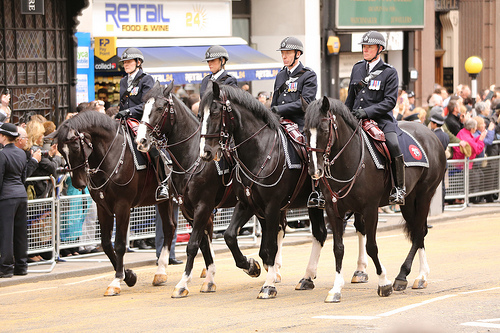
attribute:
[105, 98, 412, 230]
horses — black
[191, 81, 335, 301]
horse — black, beautiful